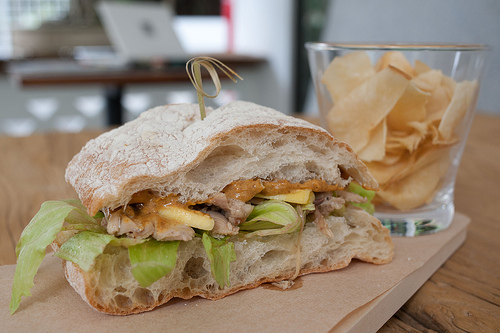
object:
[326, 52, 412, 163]
potato chips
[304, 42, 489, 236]
glass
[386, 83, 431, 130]
potato chips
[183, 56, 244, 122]
toothpick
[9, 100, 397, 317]
sandwich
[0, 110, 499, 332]
table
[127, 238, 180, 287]
lettuce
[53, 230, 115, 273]
lettuce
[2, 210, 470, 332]
paper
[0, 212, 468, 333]
board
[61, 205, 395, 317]
bread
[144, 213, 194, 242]
meat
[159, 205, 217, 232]
cheese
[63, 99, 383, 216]
bread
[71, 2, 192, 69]
laptop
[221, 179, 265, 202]
sauce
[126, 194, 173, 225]
sauce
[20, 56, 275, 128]
table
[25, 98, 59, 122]
light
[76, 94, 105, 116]
light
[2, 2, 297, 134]
wall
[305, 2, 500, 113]
wall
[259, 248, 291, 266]
hole